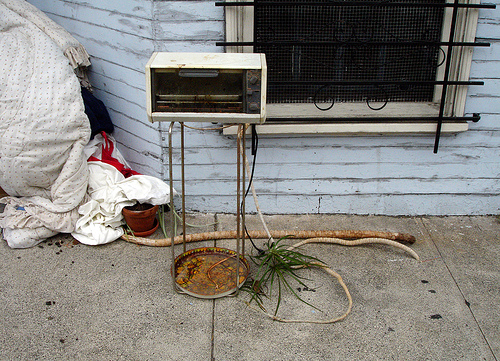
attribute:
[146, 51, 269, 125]
toaster oven — white, used, dirty, old, broken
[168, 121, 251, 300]
plant stand — rusty, metal, small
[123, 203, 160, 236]
pot — small, red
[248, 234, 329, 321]
plant — green, out of place, small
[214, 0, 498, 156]
security bars — black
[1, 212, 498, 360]
sidewalk — concrete, cement, grey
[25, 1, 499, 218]
siding — light blue, clapboard, pale blue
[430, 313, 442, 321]
stain — black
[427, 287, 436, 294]
stain — black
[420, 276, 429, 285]
stain — black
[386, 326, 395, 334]
stain — black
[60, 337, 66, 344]
stain — black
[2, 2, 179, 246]
clothing — polka dot, white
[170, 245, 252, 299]
tray — rusty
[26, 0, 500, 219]
house — blue, white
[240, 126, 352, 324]
cor — very long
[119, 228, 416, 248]
wood — long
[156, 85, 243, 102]
sheet — gray